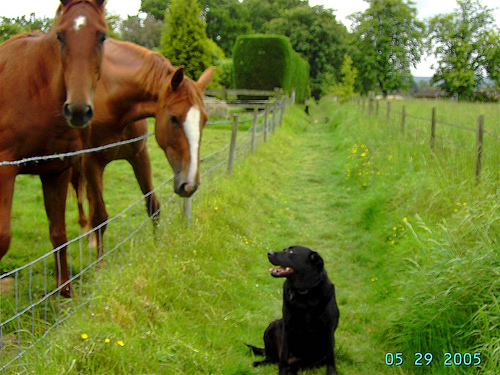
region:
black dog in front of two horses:
[260, 228, 348, 373]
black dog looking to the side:
[261, 234, 332, 373]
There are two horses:
[18, 15, 224, 251]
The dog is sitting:
[235, 205, 330, 360]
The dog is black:
[240, 235, 340, 365]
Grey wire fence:
[25, 55, 287, 346]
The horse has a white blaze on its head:
[141, 60, 211, 200]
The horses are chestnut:
[7, 6, 218, 272]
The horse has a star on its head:
[43, 6, 112, 138]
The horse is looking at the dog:
[113, 44, 356, 358]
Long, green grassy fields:
[1, 108, 485, 355]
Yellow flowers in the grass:
[348, 124, 457, 279]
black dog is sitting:
[224, 214, 352, 338]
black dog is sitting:
[160, 102, 355, 366]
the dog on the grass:
[245, 241, 342, 371]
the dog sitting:
[245, 244, 342, 374]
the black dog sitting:
[244, 243, 343, 373]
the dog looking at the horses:
[246, 246, 342, 373]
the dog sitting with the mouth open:
[245, 242, 342, 373]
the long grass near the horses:
[113, 233, 229, 368]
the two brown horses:
[0, 0, 215, 295]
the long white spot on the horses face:
[183, 103, 200, 192]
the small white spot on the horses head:
[70, 13, 87, 33]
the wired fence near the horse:
[16, 114, 256, 369]